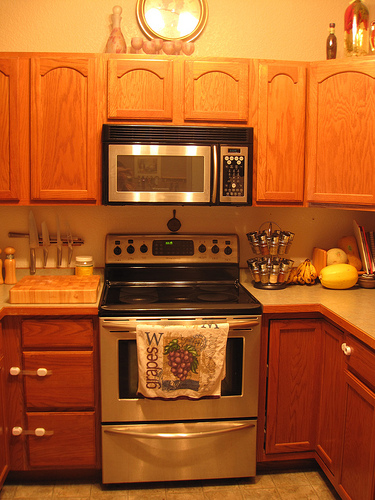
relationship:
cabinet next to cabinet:
[106, 56, 178, 125] [180, 57, 254, 125]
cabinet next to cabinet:
[180, 57, 254, 125] [254, 59, 310, 210]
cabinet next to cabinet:
[254, 59, 310, 210] [180, 57, 254, 125]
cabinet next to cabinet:
[180, 57, 254, 125] [106, 56, 178, 125]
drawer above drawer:
[21, 319, 96, 350] [23, 347, 98, 411]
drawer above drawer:
[23, 347, 98, 411] [23, 407, 100, 472]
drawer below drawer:
[23, 347, 98, 411] [21, 319, 96, 350]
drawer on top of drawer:
[21, 319, 96, 350] [23, 347, 98, 411]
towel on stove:
[133, 321, 229, 399] [100, 234, 264, 488]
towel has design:
[133, 321, 229, 399] [143, 330, 204, 392]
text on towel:
[145, 331, 164, 391] [133, 321, 229, 399]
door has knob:
[2, 323, 28, 473] [8, 365, 24, 377]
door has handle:
[97, 317, 263, 421] [100, 320, 257, 328]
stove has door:
[100, 234, 264, 488] [97, 317, 263, 421]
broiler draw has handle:
[102, 417, 256, 488] [106, 423, 254, 438]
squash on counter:
[319, 261, 360, 289] [240, 266, 373, 349]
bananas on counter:
[285, 257, 318, 285] [240, 266, 373, 349]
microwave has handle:
[100, 121, 253, 207] [211, 144, 220, 204]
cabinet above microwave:
[106, 56, 178, 125] [100, 121, 253, 207]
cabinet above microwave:
[180, 57, 254, 125] [100, 121, 253, 207]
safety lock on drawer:
[16, 368, 54, 378] [23, 347, 98, 411]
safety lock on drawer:
[16, 429, 59, 438] [23, 407, 100, 472]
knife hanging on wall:
[27, 209, 41, 275] [0, 207, 374, 268]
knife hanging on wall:
[42, 217, 54, 267] [0, 207, 374, 268]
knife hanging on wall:
[54, 207, 64, 267] [0, 207, 374, 268]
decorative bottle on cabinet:
[106, 4, 128, 54] [106, 56, 178, 125]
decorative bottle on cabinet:
[129, 32, 143, 54] [106, 56, 178, 125]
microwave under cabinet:
[100, 121, 253, 207] [106, 56, 178, 125]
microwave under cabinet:
[100, 121, 253, 207] [180, 57, 254, 125]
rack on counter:
[246, 222, 296, 289] [240, 266, 373, 349]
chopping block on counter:
[7, 276, 102, 302] [0, 266, 105, 324]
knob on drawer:
[36, 366, 48, 378] [23, 347, 98, 411]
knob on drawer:
[34, 426, 46, 438] [23, 407, 100, 472]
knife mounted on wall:
[27, 209, 41, 275] [0, 207, 374, 268]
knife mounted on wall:
[42, 217, 54, 267] [0, 207, 374, 268]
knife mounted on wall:
[54, 207, 64, 267] [0, 207, 374, 268]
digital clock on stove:
[150, 239, 197, 257] [100, 234, 264, 488]